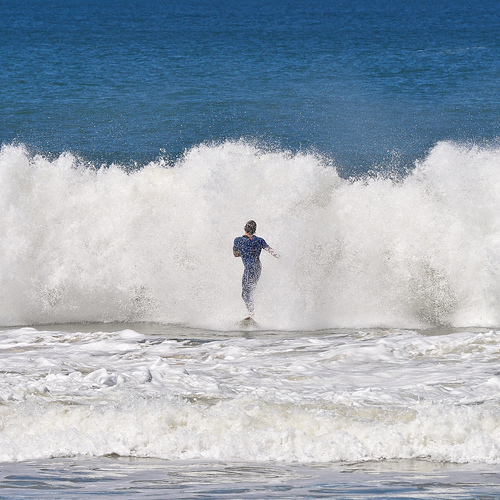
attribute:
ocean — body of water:
[1, 1, 499, 498]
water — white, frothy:
[2, 1, 497, 227]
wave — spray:
[91, 223, 431, 325]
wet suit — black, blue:
[194, 200, 309, 317]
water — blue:
[2, 2, 499, 184]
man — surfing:
[193, 185, 291, 334]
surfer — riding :
[228, 213, 281, 316]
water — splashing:
[17, 16, 489, 103]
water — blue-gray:
[5, 4, 498, 498]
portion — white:
[4, 139, 498, 471]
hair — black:
[245, 217, 258, 237]